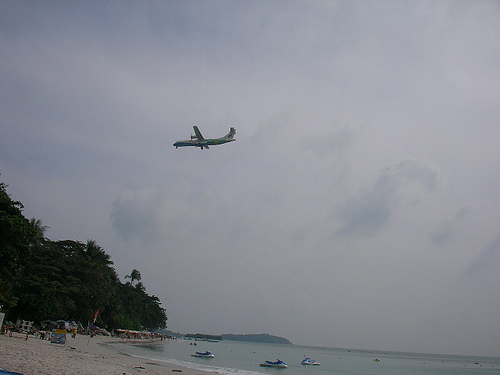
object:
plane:
[173, 125, 237, 150]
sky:
[279, 53, 380, 138]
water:
[232, 339, 285, 364]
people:
[41, 324, 78, 340]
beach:
[0, 328, 264, 375]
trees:
[46, 255, 118, 298]